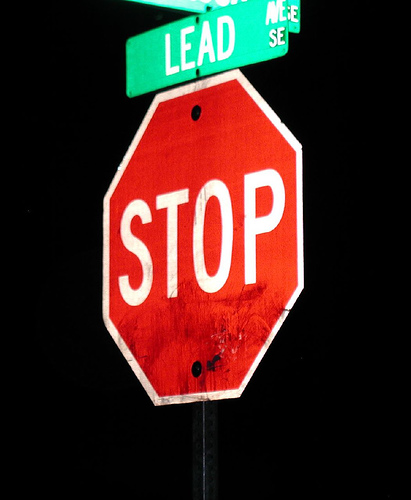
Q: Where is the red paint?
A: On the sign.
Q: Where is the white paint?
A: On the red sign.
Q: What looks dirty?
A: The stop sign.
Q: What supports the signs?
A: A pole.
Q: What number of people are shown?
A: Zero.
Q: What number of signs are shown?
A: Three.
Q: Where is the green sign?
A: Above the stop sign.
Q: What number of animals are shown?
A: Zero.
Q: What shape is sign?
A: Octagon.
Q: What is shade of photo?
A: Dark.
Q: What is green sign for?
A: Street.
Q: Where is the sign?
A: On pole.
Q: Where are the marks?
A: On stop sign.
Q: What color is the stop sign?
A: Red.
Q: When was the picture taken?
A: At night.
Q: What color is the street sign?
A: Green.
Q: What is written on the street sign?
A: Lead.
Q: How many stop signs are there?
A: One.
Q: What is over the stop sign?
A: The street sign.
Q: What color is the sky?
A: Black.